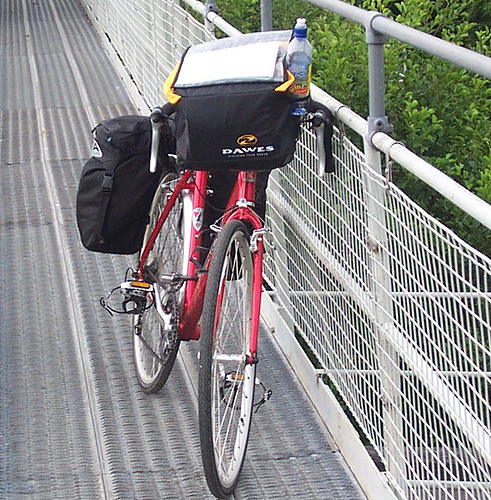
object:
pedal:
[219, 369, 273, 413]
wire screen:
[81, 0, 491, 500]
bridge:
[5, 0, 491, 500]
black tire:
[197, 217, 260, 497]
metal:
[0, 0, 375, 500]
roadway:
[0, 0, 373, 500]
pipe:
[370, 131, 491, 231]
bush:
[194, 0, 490, 262]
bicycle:
[96, 92, 343, 500]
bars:
[146, 101, 178, 175]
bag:
[170, 27, 299, 171]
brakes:
[208, 206, 270, 255]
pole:
[364, 10, 395, 136]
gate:
[79, 0, 491, 500]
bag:
[74, 114, 176, 255]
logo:
[191, 207, 205, 233]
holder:
[289, 90, 313, 130]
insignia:
[236, 134, 258, 148]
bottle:
[284, 17, 312, 117]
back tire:
[129, 168, 195, 395]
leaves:
[218, 0, 491, 254]